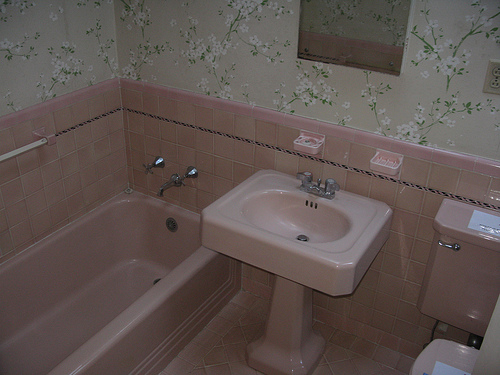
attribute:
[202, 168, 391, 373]
sink — pink, white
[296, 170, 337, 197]
faucet — silver, chrome, gray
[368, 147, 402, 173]
toothbrush holder — pink, present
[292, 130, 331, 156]
soap dish — pink, small, floral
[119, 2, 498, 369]
wall — floral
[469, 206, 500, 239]
sign — white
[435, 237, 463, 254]
handle — silver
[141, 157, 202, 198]
faucet — silver, chrome, gray, pink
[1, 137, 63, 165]
towel rack — white, pink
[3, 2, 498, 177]
wallpaper — floral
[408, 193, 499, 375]
toilet — pink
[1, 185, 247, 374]
bath tub — pink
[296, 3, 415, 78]
mirror — present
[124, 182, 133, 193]
plug — white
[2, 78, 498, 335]
tile — pink